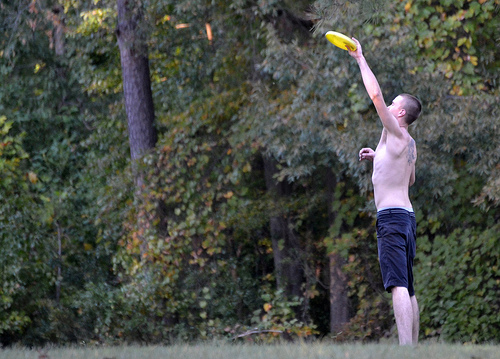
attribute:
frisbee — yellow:
[314, 23, 371, 67]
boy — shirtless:
[326, 44, 430, 309]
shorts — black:
[377, 203, 424, 297]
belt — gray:
[373, 203, 423, 221]